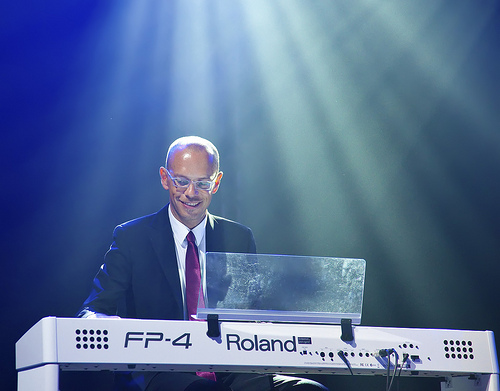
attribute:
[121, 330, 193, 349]
writing — black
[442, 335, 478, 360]
dots — black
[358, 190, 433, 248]
light — shining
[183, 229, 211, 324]
tie — maroon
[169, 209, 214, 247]
collar — white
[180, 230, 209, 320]
tie — purple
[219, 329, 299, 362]
word — Roland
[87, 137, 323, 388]
man — smiling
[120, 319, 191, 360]
letters — FP-4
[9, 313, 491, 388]
organ — grey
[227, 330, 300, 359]
word — Roland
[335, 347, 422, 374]
cords — Black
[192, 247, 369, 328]
holder — Lear, music, plastic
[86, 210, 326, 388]
suit — blue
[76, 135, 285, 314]
man — bald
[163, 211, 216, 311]
shirt — white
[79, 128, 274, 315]
man — bald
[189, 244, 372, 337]
screen — plastic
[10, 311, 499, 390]
table — gray, colored, grey